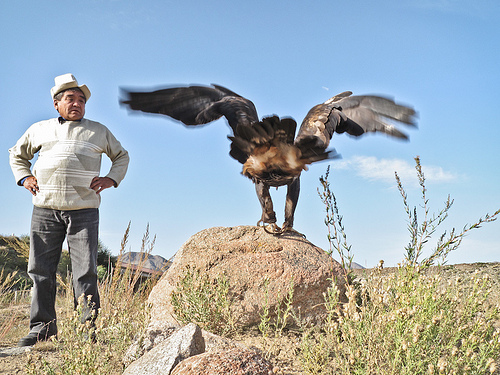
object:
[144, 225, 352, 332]
rock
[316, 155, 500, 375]
plant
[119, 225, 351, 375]
rocky area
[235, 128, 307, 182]
bird body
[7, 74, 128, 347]
man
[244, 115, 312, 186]
tail feather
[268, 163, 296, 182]
face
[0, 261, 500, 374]
desert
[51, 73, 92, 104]
hat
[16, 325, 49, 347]
shoe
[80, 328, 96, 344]
shoe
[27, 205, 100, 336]
jeans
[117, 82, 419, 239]
bird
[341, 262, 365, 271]
mountain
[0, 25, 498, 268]
background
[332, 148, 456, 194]
cloud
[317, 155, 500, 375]
grass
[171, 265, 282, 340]
plants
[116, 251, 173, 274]
mountain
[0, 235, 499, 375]
field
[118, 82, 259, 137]
left wing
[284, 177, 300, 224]
right leg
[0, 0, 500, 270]
sky